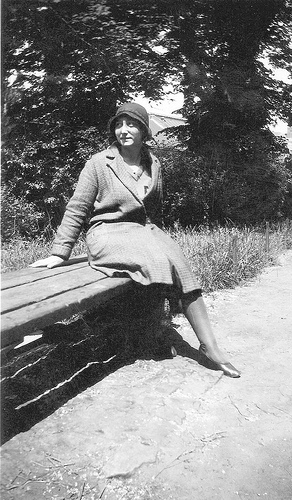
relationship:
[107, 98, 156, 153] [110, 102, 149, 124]
woman wears hat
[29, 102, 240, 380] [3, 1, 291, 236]
woman in front trees